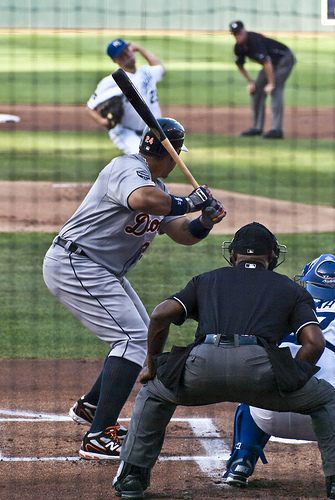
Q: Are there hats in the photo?
A: Yes, there is a hat.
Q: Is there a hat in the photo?
A: Yes, there is a hat.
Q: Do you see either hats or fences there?
A: Yes, there is a hat.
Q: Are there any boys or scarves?
A: No, there are no boys or scarves.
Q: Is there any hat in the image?
A: Yes, there is a hat.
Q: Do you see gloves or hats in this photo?
A: Yes, there is a hat.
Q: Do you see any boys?
A: No, there are no boys.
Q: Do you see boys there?
A: No, there are no boys.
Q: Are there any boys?
A: No, there are no boys.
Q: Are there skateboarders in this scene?
A: No, there are no skateboarders.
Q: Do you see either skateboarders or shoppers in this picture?
A: No, there are no skateboarders or shoppers.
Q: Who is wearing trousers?
A: The guy is wearing trousers.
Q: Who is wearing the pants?
A: The guy is wearing trousers.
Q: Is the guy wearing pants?
A: Yes, the guy is wearing pants.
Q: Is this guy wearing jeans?
A: No, the guy is wearing pants.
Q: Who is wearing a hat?
A: The guy is wearing a hat.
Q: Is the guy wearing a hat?
A: Yes, the guy is wearing a hat.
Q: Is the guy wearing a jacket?
A: No, the guy is wearing a hat.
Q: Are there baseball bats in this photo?
A: Yes, there is a baseball bat.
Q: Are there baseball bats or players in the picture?
A: Yes, there is a baseball bat.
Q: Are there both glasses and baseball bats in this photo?
A: No, there is a baseball bat but no glasses.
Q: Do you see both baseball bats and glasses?
A: No, there is a baseball bat but no glasses.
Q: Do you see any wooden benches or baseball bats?
A: Yes, there is a wood baseball bat.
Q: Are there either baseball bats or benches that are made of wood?
A: Yes, the baseball bat is made of wood.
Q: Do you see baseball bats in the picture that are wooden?
A: Yes, there is a wood baseball bat.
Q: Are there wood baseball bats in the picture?
A: Yes, there is a wood baseball bat.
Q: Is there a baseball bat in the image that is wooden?
A: Yes, there is a baseball bat that is wooden.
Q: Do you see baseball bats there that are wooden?
A: Yes, there is a baseball bat that is wooden.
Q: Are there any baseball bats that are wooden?
A: Yes, there is a baseball bat that is wooden.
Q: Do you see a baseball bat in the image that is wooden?
A: Yes, there is a baseball bat that is wooden.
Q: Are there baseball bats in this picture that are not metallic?
A: Yes, there is a wooden baseball bat.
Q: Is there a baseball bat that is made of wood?
A: Yes, there is a baseball bat that is made of wood.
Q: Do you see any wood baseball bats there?
A: Yes, there is a baseball bat that is made of wood.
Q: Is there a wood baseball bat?
A: Yes, there is a baseball bat that is made of wood.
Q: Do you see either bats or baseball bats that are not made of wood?
A: No, there is a baseball bat but it is made of wood.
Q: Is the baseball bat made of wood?
A: Yes, the baseball bat is made of wood.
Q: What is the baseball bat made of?
A: The baseball bat is made of wood.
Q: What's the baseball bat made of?
A: The baseball bat is made of wood.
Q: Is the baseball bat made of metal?
A: No, the baseball bat is made of wood.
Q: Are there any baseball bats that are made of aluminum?
A: No, there is a baseball bat but it is made of wood.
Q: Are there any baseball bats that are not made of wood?
A: No, there is a baseball bat but it is made of wood.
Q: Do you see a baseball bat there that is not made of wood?
A: No, there is a baseball bat but it is made of wood.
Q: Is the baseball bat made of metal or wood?
A: The baseball bat is made of wood.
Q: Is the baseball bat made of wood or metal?
A: The baseball bat is made of wood.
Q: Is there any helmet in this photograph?
A: Yes, there is a helmet.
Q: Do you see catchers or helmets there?
A: Yes, there is a helmet.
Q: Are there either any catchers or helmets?
A: Yes, there is a helmet.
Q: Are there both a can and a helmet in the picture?
A: No, there is a helmet but no cans.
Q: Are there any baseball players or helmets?
A: Yes, there is a baseball helmet.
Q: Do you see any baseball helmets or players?
A: Yes, there is a baseball helmet.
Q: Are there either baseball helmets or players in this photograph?
A: Yes, there is a baseball helmet.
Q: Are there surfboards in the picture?
A: No, there are no surfboards.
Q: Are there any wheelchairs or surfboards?
A: No, there are no surfboards or wheelchairs.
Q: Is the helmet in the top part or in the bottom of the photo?
A: The helmet is in the top of the image.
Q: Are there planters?
A: No, there are no planters.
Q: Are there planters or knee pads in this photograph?
A: No, there are no planters or knee pads.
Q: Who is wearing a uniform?
A: The player is wearing a uniform.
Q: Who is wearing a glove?
A: The player is wearing a glove.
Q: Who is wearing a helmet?
A: The player is wearing a helmet.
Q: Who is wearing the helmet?
A: The player is wearing a helmet.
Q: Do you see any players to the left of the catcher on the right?
A: Yes, there is a player to the left of the catcher.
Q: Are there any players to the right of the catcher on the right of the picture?
A: No, the player is to the left of the catcher.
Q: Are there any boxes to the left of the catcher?
A: No, there is a player to the left of the catcher.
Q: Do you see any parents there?
A: No, there are no parents.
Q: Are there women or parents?
A: No, there are no parents or women.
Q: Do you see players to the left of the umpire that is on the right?
A: Yes, there is a player to the left of the umpire.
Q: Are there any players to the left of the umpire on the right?
A: Yes, there is a player to the left of the umpire.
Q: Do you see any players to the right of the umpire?
A: No, the player is to the left of the umpire.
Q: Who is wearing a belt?
A: The player is wearing a belt.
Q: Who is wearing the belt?
A: The player is wearing a belt.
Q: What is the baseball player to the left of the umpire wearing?
A: The player is wearing a belt.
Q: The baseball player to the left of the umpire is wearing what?
A: The player is wearing a belt.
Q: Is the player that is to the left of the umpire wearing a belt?
A: Yes, the player is wearing a belt.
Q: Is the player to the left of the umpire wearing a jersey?
A: No, the player is wearing a belt.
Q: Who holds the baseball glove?
A: The player holds the glove.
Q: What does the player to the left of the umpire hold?
A: The player holds the glove.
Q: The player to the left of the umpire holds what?
A: The player holds the glove.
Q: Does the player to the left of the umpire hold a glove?
A: Yes, the player holds a glove.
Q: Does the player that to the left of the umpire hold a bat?
A: No, the player holds a glove.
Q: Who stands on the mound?
A: The player stands on the mound.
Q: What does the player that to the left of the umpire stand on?
A: The player stands on the mound.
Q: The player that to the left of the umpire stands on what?
A: The player stands on the mound.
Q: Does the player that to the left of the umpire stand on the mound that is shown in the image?
A: Yes, the player stands on the mound.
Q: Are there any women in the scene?
A: No, there are no women.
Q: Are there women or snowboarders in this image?
A: No, there are no women or snowboarders.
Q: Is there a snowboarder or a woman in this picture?
A: No, there are no women or snowboarders.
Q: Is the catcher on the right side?
A: Yes, the catcher is on the right of the image.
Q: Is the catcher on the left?
A: No, the catcher is on the right of the image.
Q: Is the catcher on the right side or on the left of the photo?
A: The catcher is on the right of the image.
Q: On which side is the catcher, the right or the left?
A: The catcher is on the right of the image.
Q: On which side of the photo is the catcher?
A: The catcher is on the right of the image.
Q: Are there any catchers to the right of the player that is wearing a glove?
A: Yes, there is a catcher to the right of the player.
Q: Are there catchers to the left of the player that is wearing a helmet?
A: No, the catcher is to the right of the player.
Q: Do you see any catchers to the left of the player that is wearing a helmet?
A: No, the catcher is to the right of the player.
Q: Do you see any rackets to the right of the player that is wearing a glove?
A: No, there is a catcher to the right of the player.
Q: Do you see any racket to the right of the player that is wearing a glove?
A: No, there is a catcher to the right of the player.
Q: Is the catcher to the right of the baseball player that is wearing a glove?
A: Yes, the catcher is to the right of the player.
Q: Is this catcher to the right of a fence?
A: No, the catcher is to the right of the player.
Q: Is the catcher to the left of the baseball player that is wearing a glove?
A: No, the catcher is to the right of the player.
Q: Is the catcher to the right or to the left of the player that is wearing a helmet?
A: The catcher is to the right of the player.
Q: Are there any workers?
A: No, there are no workers.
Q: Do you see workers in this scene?
A: No, there are no workers.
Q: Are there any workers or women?
A: No, there are no workers or women.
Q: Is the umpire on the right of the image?
A: Yes, the umpire is on the right of the image.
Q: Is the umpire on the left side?
A: No, the umpire is on the right of the image.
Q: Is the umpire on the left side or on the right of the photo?
A: The umpire is on the right of the image.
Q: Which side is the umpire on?
A: The umpire is on the right of the image.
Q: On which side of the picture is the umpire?
A: The umpire is on the right of the image.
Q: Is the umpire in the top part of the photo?
A: Yes, the umpire is in the top of the image.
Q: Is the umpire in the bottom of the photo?
A: No, the umpire is in the top of the image.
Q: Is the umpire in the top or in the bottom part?
A: The umpire is in the top of the image.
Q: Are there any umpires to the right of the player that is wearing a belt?
A: Yes, there is an umpire to the right of the player.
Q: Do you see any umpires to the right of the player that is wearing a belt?
A: Yes, there is an umpire to the right of the player.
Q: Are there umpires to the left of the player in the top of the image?
A: No, the umpire is to the right of the player.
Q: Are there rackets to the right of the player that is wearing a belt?
A: No, there is an umpire to the right of the player.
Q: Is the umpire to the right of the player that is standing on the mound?
A: Yes, the umpire is to the right of the player.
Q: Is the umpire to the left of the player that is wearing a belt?
A: No, the umpire is to the right of the player.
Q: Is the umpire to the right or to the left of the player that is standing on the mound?
A: The umpire is to the right of the player.